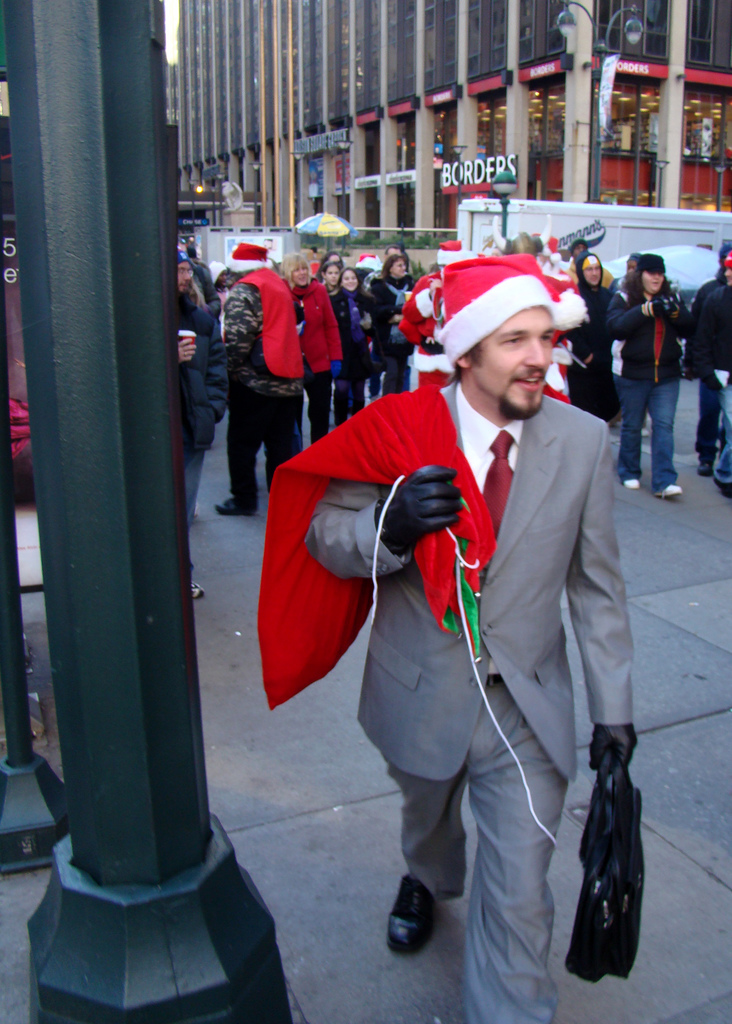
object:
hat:
[435, 244, 555, 367]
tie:
[477, 429, 516, 583]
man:
[301, 249, 634, 1019]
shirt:
[455, 378, 525, 542]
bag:
[257, 375, 499, 725]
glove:
[589, 723, 637, 769]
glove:
[373, 455, 466, 553]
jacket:
[308, 380, 640, 782]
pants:
[389, 673, 575, 1021]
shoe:
[382, 873, 442, 960]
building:
[184, 0, 721, 276]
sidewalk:
[9, 328, 727, 1013]